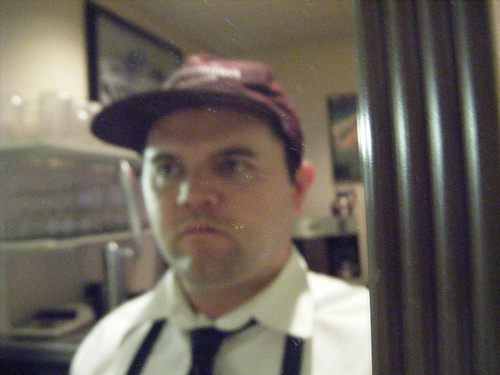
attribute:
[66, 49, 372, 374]
worker — man, staring, light skinned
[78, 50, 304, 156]
hat — red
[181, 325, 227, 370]
tie — black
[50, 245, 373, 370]
shirt — white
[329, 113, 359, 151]
train — red, silver